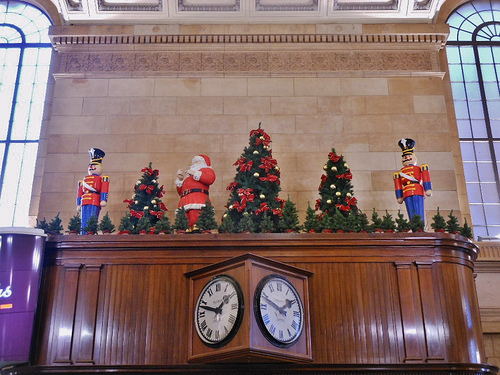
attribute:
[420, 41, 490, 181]
window — paned, glass, small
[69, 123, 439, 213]
decorations — christmas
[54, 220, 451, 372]
shelf — wooden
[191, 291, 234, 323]
hand — minute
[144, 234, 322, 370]
cube — half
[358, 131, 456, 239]
decoration — soldier, toy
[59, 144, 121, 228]
decoration — soldier, nutcracker style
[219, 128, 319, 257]
tree — christmas, decorated, small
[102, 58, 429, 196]
wall — marble, brick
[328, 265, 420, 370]
platform — wooden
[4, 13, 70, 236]
window — paned, curved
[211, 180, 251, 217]
bow — christmas, decorative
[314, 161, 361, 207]
ornament — christmas, golden, small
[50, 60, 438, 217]
wall — brown, brick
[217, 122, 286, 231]
tree — christmas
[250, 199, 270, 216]
bows — red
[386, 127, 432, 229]
soldier — wooden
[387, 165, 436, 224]
uniform — red, blue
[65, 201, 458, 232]
trees — several, small, christmas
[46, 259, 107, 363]
pillars — wood, engraved, decorative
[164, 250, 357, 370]
clocks — round 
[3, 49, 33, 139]
sun — shining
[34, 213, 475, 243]
trees — tiny, christmas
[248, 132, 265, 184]
balls — gold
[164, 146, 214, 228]
santa — figurine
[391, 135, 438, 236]
doll — nutcracker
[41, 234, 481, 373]
mantle — wooden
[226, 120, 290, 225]
tree — small, decorated, Christmas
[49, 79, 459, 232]
wall — tan, brick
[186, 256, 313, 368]
directions — opposite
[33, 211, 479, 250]
trees — tiny, evergreen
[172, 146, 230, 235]
figurine — small, Santa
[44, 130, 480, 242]
display — Christmas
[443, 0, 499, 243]
window — large, arch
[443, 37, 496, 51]
trim — black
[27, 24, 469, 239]
wall — brick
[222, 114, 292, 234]
tree — Christmas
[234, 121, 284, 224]
bows — red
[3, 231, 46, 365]
sign — purple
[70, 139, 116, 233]
mannequin — nutcracker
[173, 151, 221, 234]
figure — santa claus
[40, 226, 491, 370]
platform — brown, wooden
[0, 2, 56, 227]
window — long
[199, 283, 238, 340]
face — white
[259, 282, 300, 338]
face — white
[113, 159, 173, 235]
tree — red, gold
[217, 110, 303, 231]
tree — red, gold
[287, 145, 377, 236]
tree — red, gold